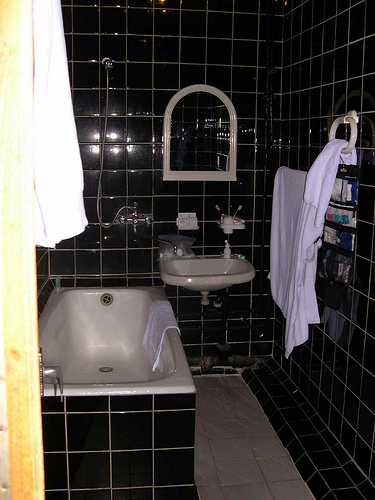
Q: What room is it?
A: It is a bathroom.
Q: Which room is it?
A: It is a bathroom.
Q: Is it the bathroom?
A: Yes, it is the bathroom.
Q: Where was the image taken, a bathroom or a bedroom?
A: It was taken at a bathroom.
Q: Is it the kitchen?
A: No, it is the bathroom.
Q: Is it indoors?
A: Yes, it is indoors.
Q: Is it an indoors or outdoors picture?
A: It is indoors.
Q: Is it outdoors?
A: No, it is indoors.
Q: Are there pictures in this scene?
A: No, there are no pictures.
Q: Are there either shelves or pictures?
A: No, there are no pictures or shelves.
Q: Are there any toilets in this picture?
A: No, there are no toilets.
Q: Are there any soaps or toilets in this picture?
A: No, there are no toilets or soaps.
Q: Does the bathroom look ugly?
A: Yes, the bathroom is ugly.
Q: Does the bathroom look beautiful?
A: No, the bathroom is ugly.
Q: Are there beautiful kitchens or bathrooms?
A: No, there is a bathroom but it is ugly.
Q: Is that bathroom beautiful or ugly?
A: The bathroom is ugly.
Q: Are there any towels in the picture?
A: Yes, there is a towel.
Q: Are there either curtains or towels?
A: Yes, there is a towel.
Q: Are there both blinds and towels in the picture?
A: No, there is a towel but no blinds.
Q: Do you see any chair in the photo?
A: No, there are no chairs.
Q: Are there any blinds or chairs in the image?
A: No, there are no chairs or blinds.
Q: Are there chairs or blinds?
A: No, there are no chairs or blinds.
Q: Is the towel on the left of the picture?
A: No, the towel is on the right of the image.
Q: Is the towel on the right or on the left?
A: The towel is on the right of the image.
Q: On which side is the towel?
A: The towel is on the right of the image.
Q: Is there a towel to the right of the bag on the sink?
A: Yes, there is a towel to the right of the bag.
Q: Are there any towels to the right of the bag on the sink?
A: Yes, there is a towel to the right of the bag.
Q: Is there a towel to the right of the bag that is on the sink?
A: Yes, there is a towel to the right of the bag.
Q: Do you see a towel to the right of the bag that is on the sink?
A: Yes, there is a towel to the right of the bag.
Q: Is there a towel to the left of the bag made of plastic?
A: No, the towel is to the right of the bag.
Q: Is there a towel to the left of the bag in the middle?
A: No, the towel is to the right of the bag.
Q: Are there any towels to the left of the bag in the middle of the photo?
A: No, the towel is to the right of the bag.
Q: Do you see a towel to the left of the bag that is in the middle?
A: No, the towel is to the right of the bag.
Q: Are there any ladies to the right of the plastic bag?
A: No, there is a towel to the right of the bag.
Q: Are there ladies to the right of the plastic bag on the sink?
A: No, there is a towel to the right of the bag.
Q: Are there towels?
A: Yes, there is a towel.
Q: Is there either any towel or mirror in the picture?
A: Yes, there is a towel.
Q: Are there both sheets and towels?
A: No, there is a towel but no sheets.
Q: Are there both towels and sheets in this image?
A: No, there is a towel but no sheets.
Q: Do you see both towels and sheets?
A: No, there is a towel but no sheets.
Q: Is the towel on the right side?
A: Yes, the towel is on the right of the image.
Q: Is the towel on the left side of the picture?
A: No, the towel is on the right of the image.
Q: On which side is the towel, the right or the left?
A: The towel is on the right of the image.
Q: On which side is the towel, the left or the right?
A: The towel is on the right of the image.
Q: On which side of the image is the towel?
A: The towel is on the right of the image.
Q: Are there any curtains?
A: No, there are no curtains.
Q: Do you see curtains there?
A: No, there are no curtains.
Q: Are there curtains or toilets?
A: No, there are no curtains or toilets.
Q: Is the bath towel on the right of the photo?
A: Yes, the bath towel is on the right of the image.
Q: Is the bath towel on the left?
A: No, the bath towel is on the right of the image.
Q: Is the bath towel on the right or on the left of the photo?
A: The bath towel is on the right of the image.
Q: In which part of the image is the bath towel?
A: The bath towel is on the right of the image.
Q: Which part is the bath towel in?
A: The bath towel is on the right of the image.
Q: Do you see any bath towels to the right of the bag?
A: Yes, there is a bath towel to the right of the bag.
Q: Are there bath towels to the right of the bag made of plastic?
A: Yes, there is a bath towel to the right of the bag.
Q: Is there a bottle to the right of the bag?
A: No, there is a bath towel to the right of the bag.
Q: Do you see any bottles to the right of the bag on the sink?
A: No, there is a bath towel to the right of the bag.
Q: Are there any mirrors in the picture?
A: Yes, there is a mirror.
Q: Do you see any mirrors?
A: Yes, there is a mirror.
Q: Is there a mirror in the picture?
A: Yes, there is a mirror.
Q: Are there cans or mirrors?
A: Yes, there is a mirror.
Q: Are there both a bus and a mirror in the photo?
A: No, there is a mirror but no buses.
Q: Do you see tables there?
A: No, there are no tables.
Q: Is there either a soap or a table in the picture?
A: No, there are no tables or soaps.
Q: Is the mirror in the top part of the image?
A: Yes, the mirror is in the top of the image.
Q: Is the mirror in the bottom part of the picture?
A: No, the mirror is in the top of the image.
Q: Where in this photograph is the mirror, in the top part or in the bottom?
A: The mirror is in the top of the image.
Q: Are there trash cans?
A: No, there are no trash cans.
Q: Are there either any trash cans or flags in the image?
A: No, there are no trash cans or flags.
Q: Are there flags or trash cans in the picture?
A: No, there are no trash cans or flags.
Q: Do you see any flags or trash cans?
A: No, there are no trash cans or flags.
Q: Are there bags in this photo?
A: Yes, there is a bag.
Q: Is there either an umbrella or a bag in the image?
A: Yes, there is a bag.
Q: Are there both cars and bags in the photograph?
A: No, there is a bag but no cars.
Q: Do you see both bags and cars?
A: No, there is a bag but no cars.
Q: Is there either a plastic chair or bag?
A: Yes, there is a plastic bag.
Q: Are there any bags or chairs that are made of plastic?
A: Yes, the bag is made of plastic.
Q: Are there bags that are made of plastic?
A: Yes, there is a bag that is made of plastic.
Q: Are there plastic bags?
A: Yes, there is a bag that is made of plastic.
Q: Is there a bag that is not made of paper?
A: Yes, there is a bag that is made of plastic.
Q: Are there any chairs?
A: No, there are no chairs.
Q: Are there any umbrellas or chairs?
A: No, there are no chairs or umbrellas.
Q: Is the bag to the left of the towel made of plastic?
A: Yes, the bag is made of plastic.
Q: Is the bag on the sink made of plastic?
A: Yes, the bag is made of plastic.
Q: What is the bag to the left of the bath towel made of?
A: The bag is made of plastic.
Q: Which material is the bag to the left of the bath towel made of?
A: The bag is made of plastic.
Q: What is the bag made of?
A: The bag is made of plastic.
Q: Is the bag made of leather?
A: No, the bag is made of plastic.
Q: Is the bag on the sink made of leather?
A: No, the bag is made of plastic.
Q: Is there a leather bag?
A: No, there is a bag but it is made of plastic.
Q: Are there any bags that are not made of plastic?
A: No, there is a bag but it is made of plastic.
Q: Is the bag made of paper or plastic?
A: The bag is made of plastic.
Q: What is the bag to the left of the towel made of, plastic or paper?
A: The bag is made of plastic.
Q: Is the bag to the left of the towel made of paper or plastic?
A: The bag is made of plastic.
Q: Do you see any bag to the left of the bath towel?
A: Yes, there is a bag to the left of the bath towel.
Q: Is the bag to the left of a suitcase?
A: No, the bag is to the left of the bath towel.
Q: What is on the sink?
A: The bag is on the sink.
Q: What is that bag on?
A: The bag is on the sink.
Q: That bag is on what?
A: The bag is on the sink.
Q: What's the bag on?
A: The bag is on the sink.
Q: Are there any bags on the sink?
A: Yes, there is a bag on the sink.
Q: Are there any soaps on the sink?
A: No, there is a bag on the sink.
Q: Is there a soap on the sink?
A: No, there is a bag on the sink.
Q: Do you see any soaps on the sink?
A: No, there is a bag on the sink.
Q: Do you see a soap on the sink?
A: No, there is a bag on the sink.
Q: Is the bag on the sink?
A: Yes, the bag is on the sink.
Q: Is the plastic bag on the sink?
A: Yes, the bag is on the sink.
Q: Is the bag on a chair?
A: No, the bag is on the sink.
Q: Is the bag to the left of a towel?
A: Yes, the bag is to the left of a towel.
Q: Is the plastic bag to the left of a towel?
A: Yes, the bag is to the left of a towel.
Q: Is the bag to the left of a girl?
A: No, the bag is to the left of a towel.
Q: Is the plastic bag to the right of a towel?
A: No, the bag is to the left of a towel.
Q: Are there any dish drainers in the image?
A: No, there are no dish drainers.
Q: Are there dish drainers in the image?
A: No, there are no dish drainers.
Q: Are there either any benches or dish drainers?
A: No, there are no dish drainers or benches.